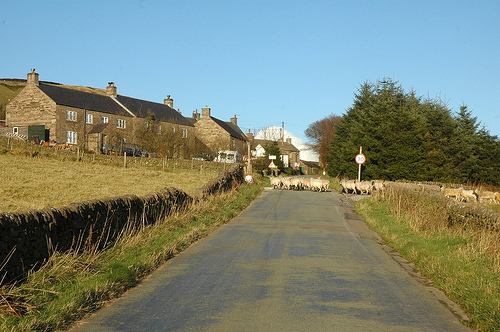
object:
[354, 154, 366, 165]
sign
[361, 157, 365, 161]
numbers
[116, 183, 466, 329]
road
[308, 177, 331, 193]
cows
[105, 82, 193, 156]
building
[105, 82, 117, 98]
chimney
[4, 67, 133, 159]
building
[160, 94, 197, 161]
building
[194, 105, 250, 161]
building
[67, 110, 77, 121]
windows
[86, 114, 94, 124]
windows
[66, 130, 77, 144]
windows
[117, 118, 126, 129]
windows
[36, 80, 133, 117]
roof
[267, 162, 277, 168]
sign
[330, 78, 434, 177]
trees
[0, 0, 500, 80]
sky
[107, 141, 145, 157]
car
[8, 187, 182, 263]
fence